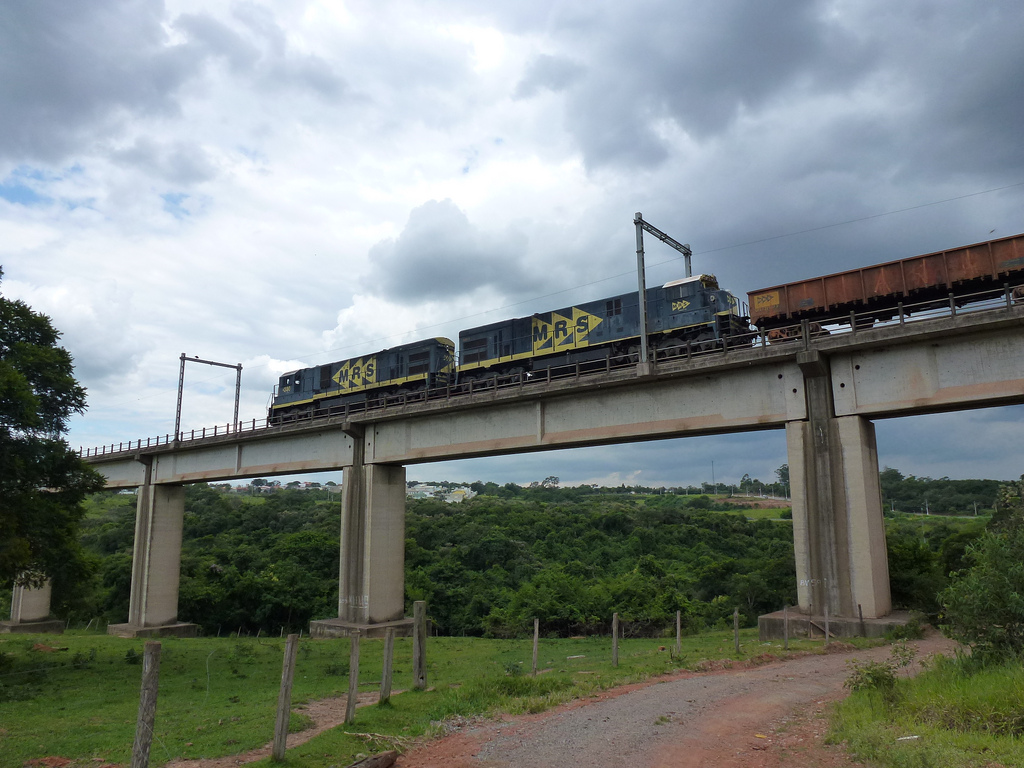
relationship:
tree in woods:
[445, 556, 538, 598] [94, 505, 807, 622]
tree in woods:
[546, 530, 595, 641] [32, 502, 1016, 640]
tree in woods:
[582, 534, 668, 640] [21, 517, 1023, 641]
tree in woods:
[877, 518, 936, 599] [18, 502, 1017, 600]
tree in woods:
[912, 515, 964, 563] [6, 515, 1022, 670]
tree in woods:
[224, 517, 329, 620] [3, 523, 1013, 621]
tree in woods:
[180, 526, 273, 621] [0, 464, 1007, 620]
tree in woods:
[264, 562, 312, 611] [30, 502, 998, 611]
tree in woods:
[44, 537, 137, 595] [6, 488, 1012, 596]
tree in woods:
[50, 482, 150, 549] [50, 482, 1016, 606]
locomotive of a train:
[261, 328, 464, 417] [261, 239, 1007, 417]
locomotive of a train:
[458, 253, 731, 397] [259, 223, 1016, 398]